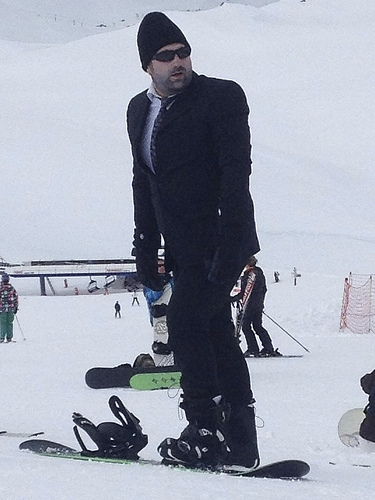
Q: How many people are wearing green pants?
A: 1.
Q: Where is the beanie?
A: On the man's head.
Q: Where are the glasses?
A: Over the man's eyes.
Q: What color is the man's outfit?
A: Black.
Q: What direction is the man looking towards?
A: The right.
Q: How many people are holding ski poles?
A: 2.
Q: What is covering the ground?
A: Snow.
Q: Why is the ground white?
A: Due to snowfall.